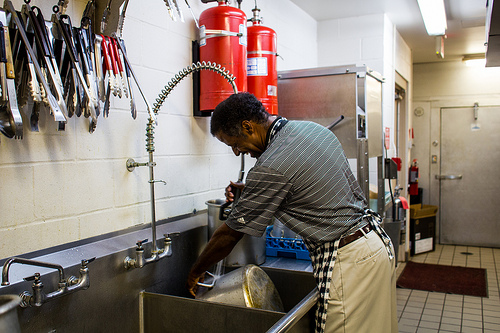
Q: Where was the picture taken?
A: In a kitchen.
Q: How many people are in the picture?
A: 1.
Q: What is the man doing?
A: Washing dishes.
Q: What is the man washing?
A: A pot.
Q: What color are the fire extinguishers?
A: Red.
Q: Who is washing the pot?
A: A man.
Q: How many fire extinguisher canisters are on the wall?
A: Two.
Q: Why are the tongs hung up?
A: To dry.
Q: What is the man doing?
A: Washing a pot.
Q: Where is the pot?
A: In the sink.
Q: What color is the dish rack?
A: Blue.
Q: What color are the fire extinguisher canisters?
A: Red.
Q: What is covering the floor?
A: Tiles.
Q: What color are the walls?
A: White.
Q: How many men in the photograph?
A: One.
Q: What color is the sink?
A: Gray.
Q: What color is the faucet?
A: Gray.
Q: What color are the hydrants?
A: Red.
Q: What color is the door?
A: Gray.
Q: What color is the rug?
A: Brown.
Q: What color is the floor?
A: Gray.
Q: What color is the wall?
A: White.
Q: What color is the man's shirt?
A: Grey.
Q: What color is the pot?
A: Gray.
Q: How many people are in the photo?
A: One.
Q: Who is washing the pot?
A: A man with a striped shirt.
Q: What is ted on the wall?
A: 2 red tanks.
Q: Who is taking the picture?
A: A co-worker.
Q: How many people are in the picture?
A: 1.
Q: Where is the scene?
A: A kitchen.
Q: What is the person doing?
A: Washing a pot.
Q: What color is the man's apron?
A: Black and white.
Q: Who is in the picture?
A: A man.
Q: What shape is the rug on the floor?
A: Square.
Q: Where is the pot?
A: In the sink.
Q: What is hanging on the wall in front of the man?
A: Utensils.